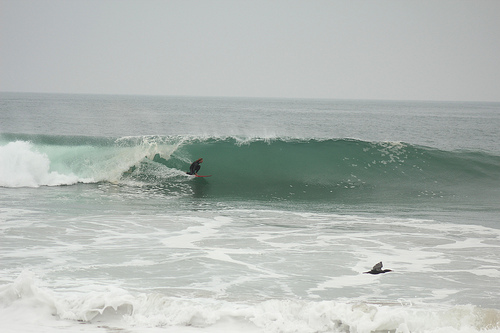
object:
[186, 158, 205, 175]
surfer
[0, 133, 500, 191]
wave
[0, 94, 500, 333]
ocean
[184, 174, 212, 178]
board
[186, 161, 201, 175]
wetsuit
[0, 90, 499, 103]
horizon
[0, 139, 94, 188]
foam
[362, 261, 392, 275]
bird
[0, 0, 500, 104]
sky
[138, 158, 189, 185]
wake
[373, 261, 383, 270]
wing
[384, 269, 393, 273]
head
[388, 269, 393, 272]
beak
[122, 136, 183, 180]
curl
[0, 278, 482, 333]
wave